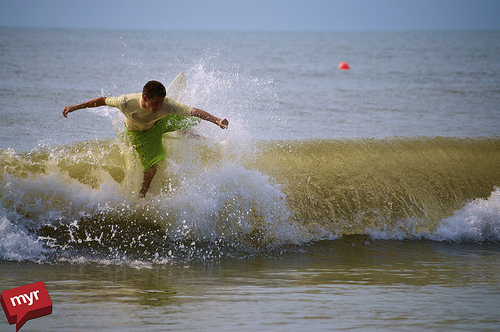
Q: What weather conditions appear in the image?
A: It is clear.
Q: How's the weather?
A: It is clear.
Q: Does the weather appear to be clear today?
A: Yes, it is clear.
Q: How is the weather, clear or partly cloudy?
A: It is clear.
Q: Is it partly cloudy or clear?
A: It is clear.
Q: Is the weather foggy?
A: No, it is clear.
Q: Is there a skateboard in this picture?
A: No, there are no skateboards.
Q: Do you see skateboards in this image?
A: No, there are no skateboards.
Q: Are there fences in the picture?
A: No, there are no fences.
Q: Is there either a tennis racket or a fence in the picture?
A: No, there are no fences or rackets.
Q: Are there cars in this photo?
A: No, there are no cars.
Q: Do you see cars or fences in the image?
A: No, there are no cars or fences.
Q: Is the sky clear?
A: Yes, the sky is clear.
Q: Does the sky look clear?
A: Yes, the sky is clear.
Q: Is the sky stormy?
A: No, the sky is clear.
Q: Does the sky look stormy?
A: No, the sky is clear.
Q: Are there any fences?
A: No, there are no fences.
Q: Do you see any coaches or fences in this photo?
A: No, there are no fences or coaches.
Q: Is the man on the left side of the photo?
A: Yes, the man is on the left of the image.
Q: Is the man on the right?
A: No, the man is on the left of the image.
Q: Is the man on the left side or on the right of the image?
A: The man is on the left of the image.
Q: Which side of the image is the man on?
A: The man is on the left of the image.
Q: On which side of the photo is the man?
A: The man is on the left of the image.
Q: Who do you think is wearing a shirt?
A: The man is wearing a shirt.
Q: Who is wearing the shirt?
A: The man is wearing a shirt.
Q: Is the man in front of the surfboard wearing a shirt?
A: Yes, the man is wearing a shirt.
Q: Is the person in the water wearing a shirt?
A: Yes, the man is wearing a shirt.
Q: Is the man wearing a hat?
A: No, the man is wearing a shirt.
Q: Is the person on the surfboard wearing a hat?
A: No, the man is wearing a shirt.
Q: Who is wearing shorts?
A: The man is wearing shorts.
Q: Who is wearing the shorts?
A: The man is wearing shorts.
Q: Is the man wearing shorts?
A: Yes, the man is wearing shorts.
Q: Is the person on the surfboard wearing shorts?
A: Yes, the man is wearing shorts.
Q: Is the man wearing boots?
A: No, the man is wearing shorts.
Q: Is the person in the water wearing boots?
A: No, the man is wearing shorts.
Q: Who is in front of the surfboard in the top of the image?
A: The man is in front of the surfboard.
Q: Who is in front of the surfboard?
A: The man is in front of the surfboard.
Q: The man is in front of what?
A: The man is in front of the surfboard.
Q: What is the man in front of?
A: The man is in front of the surfboard.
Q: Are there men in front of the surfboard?
A: Yes, there is a man in front of the surfboard.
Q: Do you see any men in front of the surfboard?
A: Yes, there is a man in front of the surfboard.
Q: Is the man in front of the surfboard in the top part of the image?
A: Yes, the man is in front of the surfboard.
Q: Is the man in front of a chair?
A: No, the man is in front of the surfboard.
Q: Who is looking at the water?
A: The man is looking at the water.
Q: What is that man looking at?
A: The man is looking at the water.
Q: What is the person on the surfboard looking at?
A: The man is looking at the water.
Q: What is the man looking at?
A: The man is looking at the water.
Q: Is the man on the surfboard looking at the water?
A: Yes, the man is looking at the water.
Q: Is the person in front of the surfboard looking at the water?
A: Yes, the man is looking at the water.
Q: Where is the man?
A: The man is in the water.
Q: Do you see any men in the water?
A: Yes, there is a man in the water.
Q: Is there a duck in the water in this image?
A: No, there is a man in the water.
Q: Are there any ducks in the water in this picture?
A: No, there is a man in the water.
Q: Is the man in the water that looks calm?
A: Yes, the man is in the water.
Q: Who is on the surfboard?
A: The man is on the surfboard.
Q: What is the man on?
A: The man is on the surfboard.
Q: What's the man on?
A: The man is on the surfboard.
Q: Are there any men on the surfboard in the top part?
A: Yes, there is a man on the surfboard.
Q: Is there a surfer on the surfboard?
A: No, there is a man on the surfboard.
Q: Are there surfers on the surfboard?
A: No, there is a man on the surfboard.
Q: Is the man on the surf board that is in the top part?
A: Yes, the man is on the surfboard.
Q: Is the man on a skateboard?
A: No, the man is on the surfboard.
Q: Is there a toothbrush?
A: No, there are no toothbrushes.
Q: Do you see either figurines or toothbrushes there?
A: No, there are no toothbrushes or figurines.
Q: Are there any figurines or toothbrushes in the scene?
A: No, there are no toothbrushes or figurines.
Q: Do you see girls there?
A: No, there are no girls.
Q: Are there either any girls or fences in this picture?
A: No, there are no girls or fences.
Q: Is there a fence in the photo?
A: No, there are no fences.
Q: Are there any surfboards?
A: Yes, there is a surfboard.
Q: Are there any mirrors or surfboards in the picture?
A: Yes, there is a surfboard.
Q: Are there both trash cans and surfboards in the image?
A: No, there is a surfboard but no trash cans.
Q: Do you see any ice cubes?
A: No, there are no ice cubes.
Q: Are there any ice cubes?
A: No, there are no ice cubes.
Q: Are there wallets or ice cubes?
A: No, there are no ice cubes or wallets.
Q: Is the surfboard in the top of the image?
A: Yes, the surfboard is in the top of the image.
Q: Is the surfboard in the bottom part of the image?
A: No, the surfboard is in the top of the image.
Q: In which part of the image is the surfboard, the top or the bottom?
A: The surfboard is in the top of the image.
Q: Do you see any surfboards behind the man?
A: Yes, there is a surfboard behind the man.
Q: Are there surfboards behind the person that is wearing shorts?
A: Yes, there is a surfboard behind the man.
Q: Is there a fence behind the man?
A: No, there is a surfboard behind the man.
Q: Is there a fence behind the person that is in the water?
A: No, there is a surfboard behind the man.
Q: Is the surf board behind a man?
A: Yes, the surf board is behind a man.